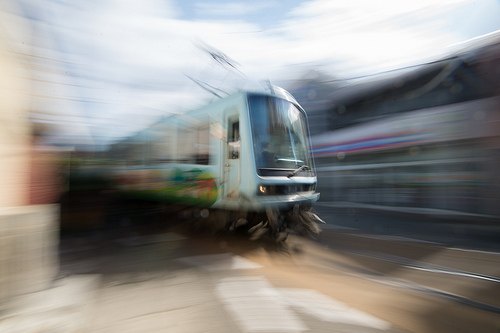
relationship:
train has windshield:
[78, 84, 320, 239] [246, 92, 318, 179]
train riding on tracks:
[78, 84, 320, 239] [274, 222, 499, 311]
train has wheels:
[78, 84, 320, 239] [118, 196, 278, 242]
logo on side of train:
[88, 169, 222, 208] [78, 84, 320, 239]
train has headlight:
[78, 84, 320, 239] [259, 183, 270, 196]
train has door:
[78, 84, 320, 239] [224, 112, 246, 198]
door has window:
[224, 112, 246, 198] [227, 118, 243, 157]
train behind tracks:
[78, 84, 320, 239] [274, 222, 499, 311]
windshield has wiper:
[246, 92, 318, 179] [287, 159, 313, 179]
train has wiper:
[78, 84, 320, 239] [287, 159, 313, 179]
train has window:
[78, 84, 320, 239] [179, 120, 216, 166]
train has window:
[78, 84, 320, 239] [146, 132, 174, 165]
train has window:
[78, 84, 320, 239] [124, 143, 148, 167]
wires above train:
[156, 26, 249, 103] [78, 84, 320, 239]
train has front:
[78, 84, 320, 239] [226, 82, 323, 207]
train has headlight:
[59, 84, 329, 246] [259, 183, 270, 196]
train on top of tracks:
[78, 84, 320, 239] [274, 222, 499, 311]